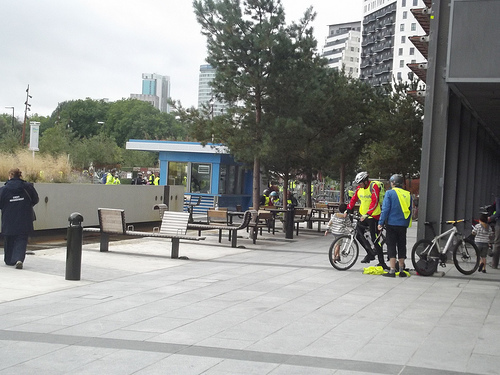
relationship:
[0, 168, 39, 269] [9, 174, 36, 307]
person wears blue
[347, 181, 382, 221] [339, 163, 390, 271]
jacket on person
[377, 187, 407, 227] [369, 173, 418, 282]
jacket on person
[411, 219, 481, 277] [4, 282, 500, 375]
bicycle parked on ground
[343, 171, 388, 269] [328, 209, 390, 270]
man walking with bicyclist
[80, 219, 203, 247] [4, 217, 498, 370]
benches on ground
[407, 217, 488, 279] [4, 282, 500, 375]
bicycle on ground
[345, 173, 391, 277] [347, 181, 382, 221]
man wearing jacket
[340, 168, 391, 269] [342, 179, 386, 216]
bicyclist wearing jacket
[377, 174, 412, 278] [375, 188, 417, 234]
man wearing jacket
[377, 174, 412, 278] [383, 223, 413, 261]
man wearing pants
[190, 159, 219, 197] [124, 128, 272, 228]
window on building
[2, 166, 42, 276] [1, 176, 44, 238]
person wearing jacket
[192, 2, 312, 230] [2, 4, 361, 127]
tree against sky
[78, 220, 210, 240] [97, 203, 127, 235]
bench with backrest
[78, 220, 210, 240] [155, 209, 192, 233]
bench with backrest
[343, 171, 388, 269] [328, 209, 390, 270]
man rides bicyclist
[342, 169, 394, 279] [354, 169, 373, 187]
man wears helmet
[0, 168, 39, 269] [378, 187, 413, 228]
person wears jacket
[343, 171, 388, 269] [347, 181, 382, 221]
man wears jacket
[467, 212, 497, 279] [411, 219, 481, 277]
girl behind bicycle